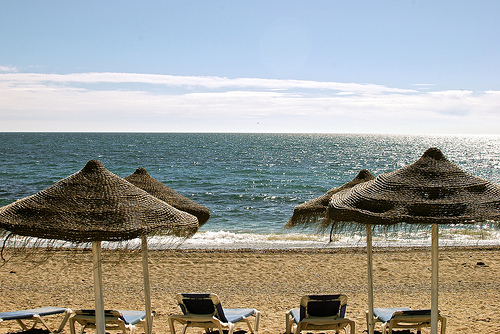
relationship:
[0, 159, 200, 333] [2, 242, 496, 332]
umbrella on beach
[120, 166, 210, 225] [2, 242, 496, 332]
umbrella on beach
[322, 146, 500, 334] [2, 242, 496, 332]
umbrella on beach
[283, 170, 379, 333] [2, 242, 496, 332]
umbrella on beach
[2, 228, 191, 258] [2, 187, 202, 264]
fringes on umbrella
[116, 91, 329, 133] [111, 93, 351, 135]
clouds fill sky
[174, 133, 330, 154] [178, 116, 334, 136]
water meet sky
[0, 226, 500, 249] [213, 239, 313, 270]
waves come ashore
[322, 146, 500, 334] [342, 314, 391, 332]
umbrella provide shade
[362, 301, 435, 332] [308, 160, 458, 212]
chair under umbrella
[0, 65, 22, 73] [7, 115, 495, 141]
clouds along horizon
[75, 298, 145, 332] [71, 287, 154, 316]
chair on beach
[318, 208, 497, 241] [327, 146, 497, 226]
fringe on a umbrella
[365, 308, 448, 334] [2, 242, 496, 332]
chair on a beach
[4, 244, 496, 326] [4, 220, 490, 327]
sand on a beach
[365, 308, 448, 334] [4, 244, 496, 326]
chair on sand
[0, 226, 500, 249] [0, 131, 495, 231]
waves on water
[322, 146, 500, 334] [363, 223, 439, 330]
umbrella on poles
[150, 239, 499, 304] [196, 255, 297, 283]
beach has footprints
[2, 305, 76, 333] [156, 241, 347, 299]
chair on beach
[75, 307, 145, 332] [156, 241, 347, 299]
chair on beach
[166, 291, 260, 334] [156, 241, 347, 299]
lounge chair on beach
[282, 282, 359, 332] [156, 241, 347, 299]
lounger on beach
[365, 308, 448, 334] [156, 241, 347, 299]
chair on beach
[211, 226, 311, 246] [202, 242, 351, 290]
waves near beach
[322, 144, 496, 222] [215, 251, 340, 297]
umbrella on beach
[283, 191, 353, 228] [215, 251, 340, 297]
umbrella on beach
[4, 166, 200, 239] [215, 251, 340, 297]
umbrella on beach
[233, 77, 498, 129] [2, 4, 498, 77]
clouds in sky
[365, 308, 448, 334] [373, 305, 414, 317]
chair to sit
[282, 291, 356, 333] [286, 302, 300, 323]
lounger to sit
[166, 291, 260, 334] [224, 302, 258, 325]
lounge chair to sit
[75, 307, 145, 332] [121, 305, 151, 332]
chair to sit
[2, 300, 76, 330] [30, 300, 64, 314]
chair to sit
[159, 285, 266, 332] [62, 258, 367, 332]
lounge chair on sand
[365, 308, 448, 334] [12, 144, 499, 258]
chair under umbrellas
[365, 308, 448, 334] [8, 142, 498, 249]
chair under umbrellas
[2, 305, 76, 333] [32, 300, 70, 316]
chair to sit